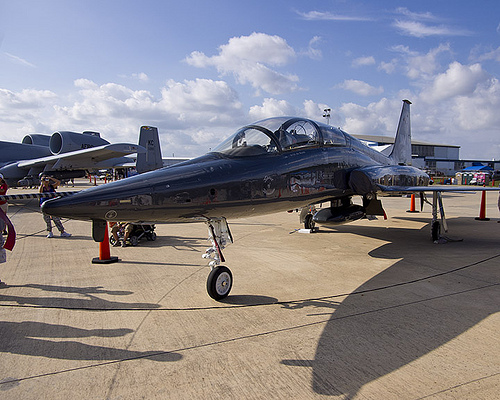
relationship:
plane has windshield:
[41, 99, 496, 300] [221, 126, 279, 156]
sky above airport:
[52, 23, 414, 124] [1, 123, 498, 301]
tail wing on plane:
[390, 97, 419, 162] [41, 99, 496, 300]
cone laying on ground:
[89, 217, 122, 266] [9, 165, 497, 394]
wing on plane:
[384, 180, 499, 194] [36, 89, 498, 319]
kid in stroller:
[100, 197, 158, 247] [98, 200, 146, 250]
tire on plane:
[198, 269, 253, 303] [41, 99, 496, 300]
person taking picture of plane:
[35, 165, 80, 237] [41, 99, 496, 300]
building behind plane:
[404, 142, 462, 171] [96, 91, 404, 262]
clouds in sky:
[6, 29, 301, 114] [52, 23, 414, 105]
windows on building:
[408, 145, 438, 153] [404, 142, 462, 171]